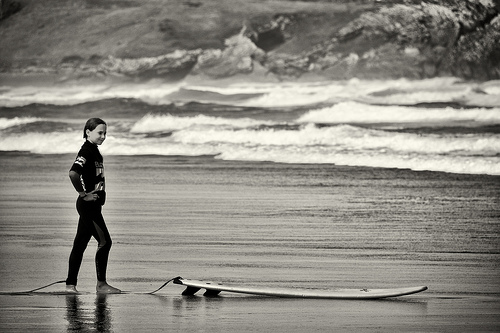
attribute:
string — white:
[0, 272, 71, 301]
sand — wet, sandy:
[12, 188, 476, 333]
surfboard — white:
[165, 269, 438, 309]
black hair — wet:
[75, 111, 112, 152]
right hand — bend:
[64, 152, 104, 204]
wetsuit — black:
[67, 144, 119, 288]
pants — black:
[65, 191, 119, 285]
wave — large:
[11, 1, 499, 76]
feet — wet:
[59, 269, 125, 303]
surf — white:
[1, 73, 499, 174]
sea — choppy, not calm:
[2, 1, 499, 174]